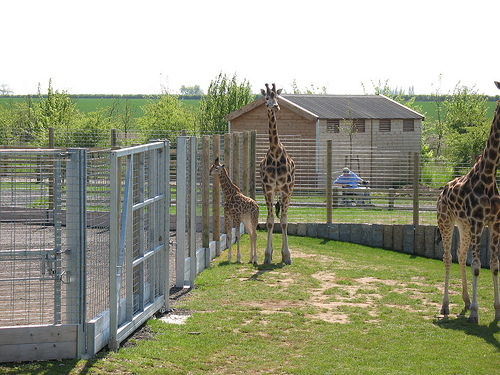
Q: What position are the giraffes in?
A: Standing.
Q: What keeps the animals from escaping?
A: A fence.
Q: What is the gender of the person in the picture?
A: Male.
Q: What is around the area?
A: A fence.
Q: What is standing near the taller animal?
A: The baby animal.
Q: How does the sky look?
A: Clear.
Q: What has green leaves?
A: Trees.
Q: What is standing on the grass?
A: Three giraffes.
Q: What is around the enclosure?
A: A fence.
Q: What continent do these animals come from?
A: Africa.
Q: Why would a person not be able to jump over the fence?
A: It is too high.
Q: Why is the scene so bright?
A: The sun is out.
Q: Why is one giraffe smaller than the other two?
A: It is a baby.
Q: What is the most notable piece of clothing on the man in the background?
A: His blue T-shirt.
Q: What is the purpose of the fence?
A: To keep the giraffes from wandering off.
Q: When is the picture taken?
A: Daytime.